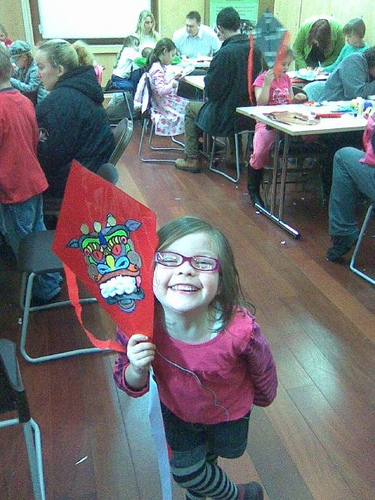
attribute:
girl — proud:
[106, 213, 275, 498]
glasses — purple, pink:
[157, 253, 220, 273]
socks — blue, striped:
[168, 462, 259, 498]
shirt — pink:
[122, 295, 277, 411]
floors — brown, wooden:
[5, 112, 374, 495]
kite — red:
[52, 159, 160, 353]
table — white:
[233, 89, 373, 245]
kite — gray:
[247, 7, 286, 72]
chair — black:
[223, 96, 259, 188]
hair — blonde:
[41, 34, 107, 75]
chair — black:
[139, 75, 186, 166]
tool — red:
[313, 114, 345, 120]